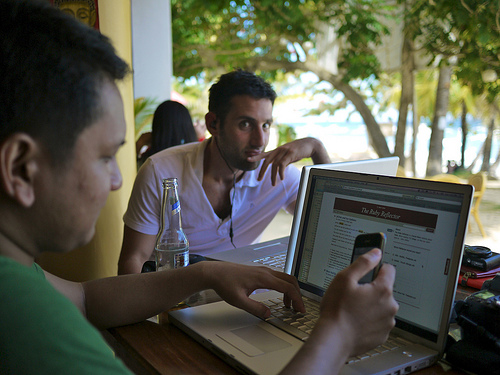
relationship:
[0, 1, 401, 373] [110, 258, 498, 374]
man sitting at table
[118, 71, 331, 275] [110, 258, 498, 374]
man sitting at table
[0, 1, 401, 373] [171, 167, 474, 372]
man using laptop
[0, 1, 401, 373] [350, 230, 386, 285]
man holding cell phone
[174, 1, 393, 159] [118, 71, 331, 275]
tree behind man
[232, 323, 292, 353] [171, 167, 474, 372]
touchpad on laptop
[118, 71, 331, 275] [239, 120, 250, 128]
man has eye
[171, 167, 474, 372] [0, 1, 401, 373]
laptop in front of man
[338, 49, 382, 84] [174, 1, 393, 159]
leaves on tree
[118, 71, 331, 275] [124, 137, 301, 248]
man wearing shirt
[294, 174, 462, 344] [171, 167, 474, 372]
screen on laptop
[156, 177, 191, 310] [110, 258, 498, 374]
bottle on table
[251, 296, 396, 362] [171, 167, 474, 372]
keyboard on laptop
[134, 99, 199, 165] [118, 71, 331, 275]
woman behind man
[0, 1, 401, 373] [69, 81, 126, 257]
man has face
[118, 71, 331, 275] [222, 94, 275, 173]
man has face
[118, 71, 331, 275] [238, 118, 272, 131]
man has eyes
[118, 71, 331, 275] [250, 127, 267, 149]
man has nose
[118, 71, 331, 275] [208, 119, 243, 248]
man wearing headphones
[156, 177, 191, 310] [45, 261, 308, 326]
bottle behind arm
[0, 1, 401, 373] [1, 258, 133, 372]
man wearing shirt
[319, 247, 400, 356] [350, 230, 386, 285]
hand holding cell phone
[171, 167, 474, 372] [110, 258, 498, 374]
laptop on table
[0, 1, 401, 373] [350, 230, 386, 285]
man using cell phone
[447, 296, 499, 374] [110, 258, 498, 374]
camera on table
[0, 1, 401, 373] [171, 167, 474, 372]
man typing on laptop